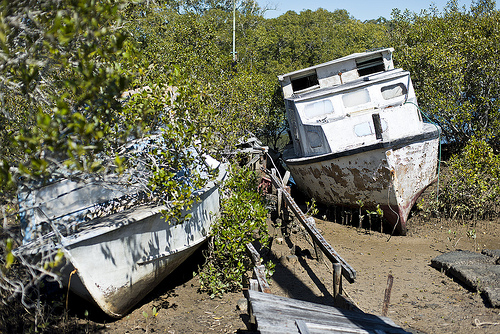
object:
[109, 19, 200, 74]
leafy trees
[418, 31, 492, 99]
leafy trees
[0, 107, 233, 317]
boat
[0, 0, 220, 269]
tree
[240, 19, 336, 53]
leafy trees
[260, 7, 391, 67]
trees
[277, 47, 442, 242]
boat